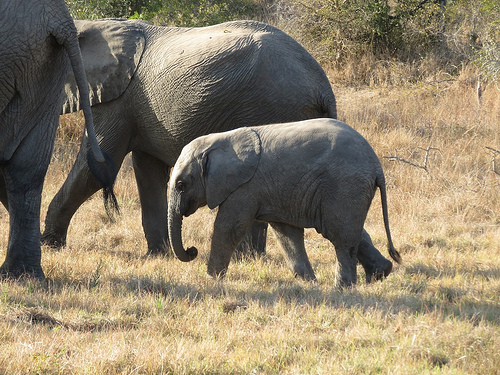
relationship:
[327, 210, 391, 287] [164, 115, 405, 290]
legs on elephant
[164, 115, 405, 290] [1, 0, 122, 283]
elephant walking with parent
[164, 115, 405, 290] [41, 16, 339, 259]
elephant walking with parent